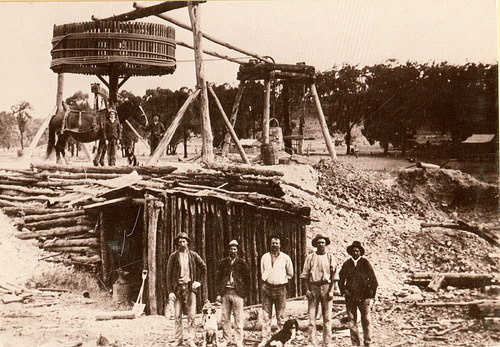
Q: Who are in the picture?
A: Men.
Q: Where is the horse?
A: On hill.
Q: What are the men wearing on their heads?
A: Hats.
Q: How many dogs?
A: Two.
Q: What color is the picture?
A: Sepia.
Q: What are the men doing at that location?
A: No indication of what.